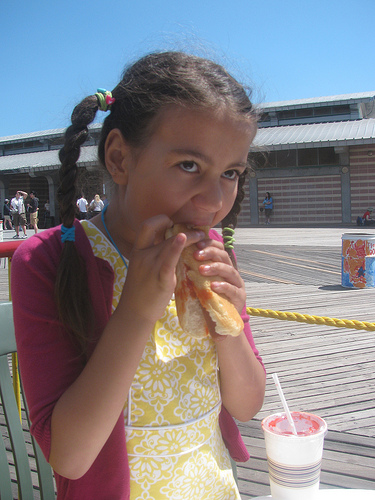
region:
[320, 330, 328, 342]
part of a floor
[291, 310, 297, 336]
part of a rope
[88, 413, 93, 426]
part of an elbow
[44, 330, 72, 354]
part of a sweater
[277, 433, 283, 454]
edge of a cup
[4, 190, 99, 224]
people standing behind the girl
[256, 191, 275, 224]
a person wearing a blue shirt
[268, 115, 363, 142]
the roof of the building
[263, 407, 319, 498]
a cup on the table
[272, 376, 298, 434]
the straw in the cup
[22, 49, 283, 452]
a girl eating a hot dog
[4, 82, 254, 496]
a girl sitting on a chair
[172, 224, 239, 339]
a hot dog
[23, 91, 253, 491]
a girl wearing a yellow dress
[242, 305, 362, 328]
a yellow rope behind the girl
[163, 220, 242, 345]
hot dog in a bun with ketchup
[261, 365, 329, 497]
white cup and straw on table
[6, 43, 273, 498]
girl eating a hot dog with ketchup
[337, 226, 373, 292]
colorful trash can on wooden ground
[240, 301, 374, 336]
yellow rope next to girl eating hot dog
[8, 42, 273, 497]
girl eating hot dog is wearing yellow outfit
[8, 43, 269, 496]
girl eating hot dog is wearing a pink sweater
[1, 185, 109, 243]
group of people in back of girl eating hot dog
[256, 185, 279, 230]
woman in blue shirt standing next to building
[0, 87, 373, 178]
roof top of building behind little girl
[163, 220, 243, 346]
a hotdog with ketchup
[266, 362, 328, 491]
a straw in a cup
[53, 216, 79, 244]
a blue hair tie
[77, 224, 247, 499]
a yellow and white floral dress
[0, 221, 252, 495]
the girl is wearing a purple cardigan over her dress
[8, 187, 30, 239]
a man blocking the sun with his left hand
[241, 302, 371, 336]
part of a yellow rope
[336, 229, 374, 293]
a trash can on the wooden ground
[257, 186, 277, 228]
a woman resting against a wall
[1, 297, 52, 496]
the back of a chair behind the girl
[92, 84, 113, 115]
hair tie on girls hair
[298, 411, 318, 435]
pink substance in cup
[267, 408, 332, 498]
white cup on table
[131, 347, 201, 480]
yellow and whtie dress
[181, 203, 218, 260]
food in mouth of girl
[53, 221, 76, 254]
blue hair tie on hair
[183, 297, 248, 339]
piece of bread in hand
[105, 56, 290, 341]
girl eating piece of food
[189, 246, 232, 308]
fingers on top of food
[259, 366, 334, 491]
A red drink with a straw.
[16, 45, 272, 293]
A girl with brown hair in pig tails.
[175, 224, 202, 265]
girl eating a hot dog bun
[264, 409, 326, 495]
a cup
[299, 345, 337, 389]
the ground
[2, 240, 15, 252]
a red pole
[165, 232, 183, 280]
the girls finger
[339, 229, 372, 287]
a trash can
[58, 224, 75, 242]
a blue hair tie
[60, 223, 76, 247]
hair tie in the hair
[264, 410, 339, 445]
a plastic cup lid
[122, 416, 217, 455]
a yellow and white dress belt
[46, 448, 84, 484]
elbow of a girl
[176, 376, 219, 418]
white design on a dress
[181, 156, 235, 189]
eyes of a girl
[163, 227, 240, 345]
ketchup covered hot dog bun